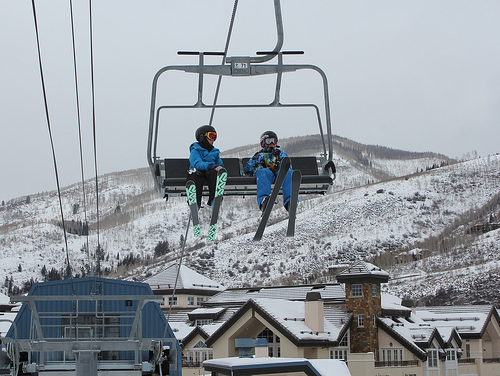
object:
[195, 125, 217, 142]
cap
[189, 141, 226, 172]
coat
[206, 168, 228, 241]
skis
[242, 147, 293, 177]
jacket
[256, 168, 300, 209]
pants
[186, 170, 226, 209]
pants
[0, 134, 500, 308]
mountain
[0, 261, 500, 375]
building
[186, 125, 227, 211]
people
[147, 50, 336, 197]
ski lift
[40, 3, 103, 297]
cable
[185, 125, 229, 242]
skier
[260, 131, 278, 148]
helmet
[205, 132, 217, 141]
goggles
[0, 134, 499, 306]
snow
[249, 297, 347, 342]
roof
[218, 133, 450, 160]
top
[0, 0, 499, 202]
sky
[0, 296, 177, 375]
lift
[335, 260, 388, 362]
chimney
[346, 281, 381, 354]
tower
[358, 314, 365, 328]
window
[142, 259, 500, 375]
lodge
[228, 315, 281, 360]
arch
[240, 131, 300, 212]
kids